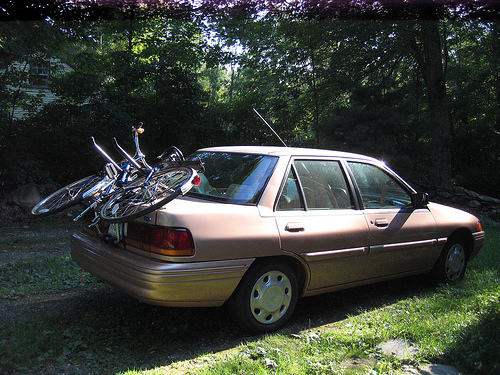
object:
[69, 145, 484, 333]
car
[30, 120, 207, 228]
bicycles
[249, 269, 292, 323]
rim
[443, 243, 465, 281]
rim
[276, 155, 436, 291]
side doors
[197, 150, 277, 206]
rear window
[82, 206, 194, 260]
tail lights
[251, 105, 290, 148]
antennae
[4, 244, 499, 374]
grass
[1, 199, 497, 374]
ground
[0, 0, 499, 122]
trees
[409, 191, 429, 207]
sideview mirror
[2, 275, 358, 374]
shadow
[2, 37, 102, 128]
house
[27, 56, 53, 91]
window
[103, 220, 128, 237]
license plate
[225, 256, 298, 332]
tire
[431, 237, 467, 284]
tire